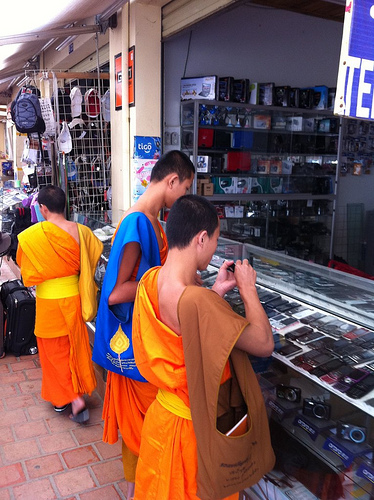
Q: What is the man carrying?
A: A purse.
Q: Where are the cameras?
A: In the case.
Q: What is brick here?
A: The sidewalk.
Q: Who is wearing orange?
A: The monks.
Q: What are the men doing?
A: Shopping.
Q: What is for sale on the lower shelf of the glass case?
A: Cameras.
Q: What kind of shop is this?
A: Electronics shop.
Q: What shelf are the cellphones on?
A: Top shelf.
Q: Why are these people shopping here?
A: To buy electronics.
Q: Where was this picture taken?
A: A street vendors kiosk.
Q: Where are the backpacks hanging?
A: A metal rack.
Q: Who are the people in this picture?
A: Young monks.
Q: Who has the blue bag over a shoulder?
A: The man in the middle.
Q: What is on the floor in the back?
A: Luggage.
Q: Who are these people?
A: Young men looking at cell phones.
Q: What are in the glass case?
A: Cell Phones.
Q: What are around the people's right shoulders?
A: Bags.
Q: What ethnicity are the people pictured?
A: Asian.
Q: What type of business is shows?
A: Retail store.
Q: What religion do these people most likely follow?
A: Buddhism.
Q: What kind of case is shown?
A: Glass case.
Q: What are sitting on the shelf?
A: Boxes.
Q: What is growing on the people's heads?
A: Hair.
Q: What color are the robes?
A: Orange.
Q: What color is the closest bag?
A: Brown.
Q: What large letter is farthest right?
A: E.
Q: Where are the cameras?
A: Second shelf.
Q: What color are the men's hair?
A: Black.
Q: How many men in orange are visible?
A: 3.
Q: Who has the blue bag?
A: Guy in middle.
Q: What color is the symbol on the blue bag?
A: Yellow.